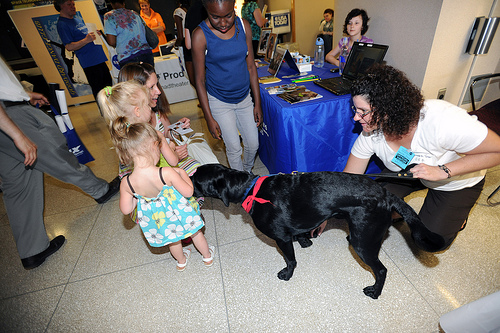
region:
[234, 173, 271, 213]
The red cloth around the dog's neck.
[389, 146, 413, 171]
The blue tag on the woman's shirt.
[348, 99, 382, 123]
The eyeglasses the woman next to the dog is wearing.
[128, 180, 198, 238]
The flower dress the little girl is wearing.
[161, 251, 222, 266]
The white sandals the little girl in the flower dress is wearing.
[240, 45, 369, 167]
The royal blue table cloth on the table.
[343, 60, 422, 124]
The curly hair of the lady next to the dog.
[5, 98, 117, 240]
The gray pants the man is wearing.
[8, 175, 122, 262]
The black shoes the man is wearing.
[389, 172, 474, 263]
The black pants the lady next to the dog is wearing.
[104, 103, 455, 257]
a black dog sniffing children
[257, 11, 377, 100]
a woman at a registration desk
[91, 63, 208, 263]
a woman kneeling down with two small toddlers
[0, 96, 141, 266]
grey suit pants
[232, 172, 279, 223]
a pink hanger chief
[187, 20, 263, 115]
a blue tank top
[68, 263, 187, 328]
a white speckled tile floor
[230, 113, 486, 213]
a woman holding a dog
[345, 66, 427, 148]
curly black hair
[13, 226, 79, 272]
a black dress shoes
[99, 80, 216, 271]
Two little girls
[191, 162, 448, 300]
Black dog next to a little girl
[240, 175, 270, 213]
Red rope on the dog's neck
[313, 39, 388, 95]
Computer on the table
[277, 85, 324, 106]
Magazine on the table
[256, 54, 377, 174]
Blue table cloth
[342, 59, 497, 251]
Woman kneeling on the ground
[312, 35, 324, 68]
Water bottle on the table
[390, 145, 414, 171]
Label on the woman's shirt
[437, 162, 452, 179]
Bracelet on the woman's wrist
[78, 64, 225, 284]
little girl in blue flowered dress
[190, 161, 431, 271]
black dog with red scarf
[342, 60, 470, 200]
woman with white shirt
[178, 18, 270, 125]
person with blue shirt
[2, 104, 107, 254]
person with grey pants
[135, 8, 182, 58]
person with orange shirt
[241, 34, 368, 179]
blue table cloth on table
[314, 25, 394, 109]
laptop on photograph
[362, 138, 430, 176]
something blue in womans hands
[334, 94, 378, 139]
woman wearing eye glasses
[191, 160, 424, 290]
a black labrador retriever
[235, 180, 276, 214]
a red bandana around a dog's neck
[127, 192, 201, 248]
yellow and white flowers on a girl's dress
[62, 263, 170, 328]
tan and grey floor tiles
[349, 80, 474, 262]
a woman with curly hair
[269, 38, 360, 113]
a blue table with items on it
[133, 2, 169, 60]
a woman in a neon orange shirt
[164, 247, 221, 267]
white sandals on a little girl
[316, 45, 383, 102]
a black laptop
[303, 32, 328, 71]
a water bottle with a blue top